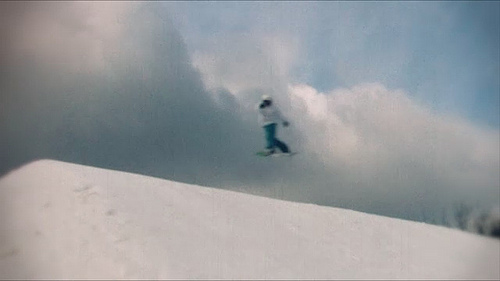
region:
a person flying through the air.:
[248, 84, 295, 161]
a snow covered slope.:
[3, 158, 498, 277]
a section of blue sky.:
[173, 8, 496, 125]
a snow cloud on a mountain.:
[0, 0, 491, 227]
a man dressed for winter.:
[254, 91, 291, 161]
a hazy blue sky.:
[168, 0, 495, 131]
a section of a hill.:
[425, 187, 489, 232]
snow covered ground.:
[0, 142, 497, 278]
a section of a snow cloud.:
[25, 37, 147, 111]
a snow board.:
[247, 139, 312, 157]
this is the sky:
[171, 15, 328, 54]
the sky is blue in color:
[305, 36, 392, 78]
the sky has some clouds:
[321, 50, 390, 135]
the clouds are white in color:
[100, 20, 163, 51]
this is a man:
[253, 88, 295, 170]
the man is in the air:
[252, 87, 298, 163]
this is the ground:
[116, 200, 213, 234]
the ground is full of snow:
[151, 201, 220, 271]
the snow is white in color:
[99, 203, 193, 269]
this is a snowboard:
[257, 150, 292, 157]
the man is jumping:
[220, 71, 320, 203]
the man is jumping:
[239, 54, 296, 174]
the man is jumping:
[215, 31, 351, 268]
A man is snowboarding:
[249, 52, 322, 184]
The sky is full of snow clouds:
[12, 12, 180, 103]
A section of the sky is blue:
[425, 16, 493, 103]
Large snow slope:
[45, 140, 257, 273]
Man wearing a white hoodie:
[247, 80, 294, 129]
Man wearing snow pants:
[249, 114, 311, 162]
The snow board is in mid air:
[250, 147, 308, 162]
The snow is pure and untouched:
[158, 190, 315, 240]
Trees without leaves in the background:
[415, 201, 495, 238]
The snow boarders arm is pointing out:
[275, 102, 300, 140]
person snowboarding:
[250, 86, 307, 173]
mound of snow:
[1, 146, 497, 278]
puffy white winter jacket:
[251, 96, 296, 127]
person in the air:
[246, 88, 306, 171]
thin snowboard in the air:
[256, 145, 301, 160]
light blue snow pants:
[255, 120, 286, 150]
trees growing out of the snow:
[408, 197, 498, 234]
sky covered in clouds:
[0, 1, 495, 223]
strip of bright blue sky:
[480, 22, 497, 95]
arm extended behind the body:
[273, 106, 292, 126]